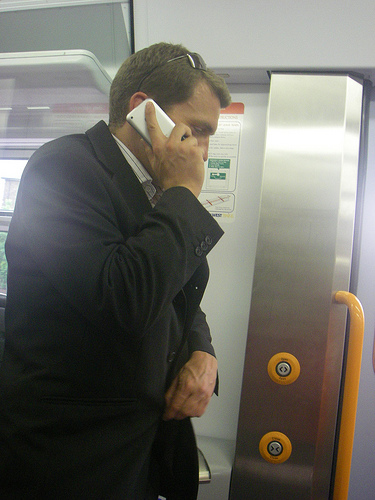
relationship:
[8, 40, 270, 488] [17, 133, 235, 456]
man wearing jacket